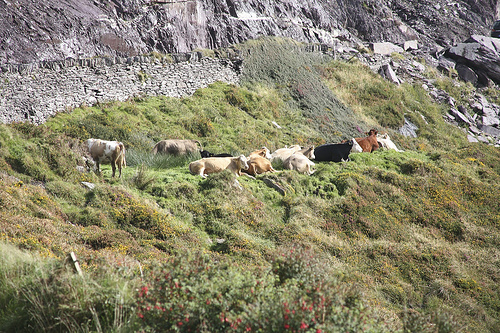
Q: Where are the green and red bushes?
A: Front of grass.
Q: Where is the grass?
A: Behind the bushes.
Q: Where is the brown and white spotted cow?
A: Left of the other animals.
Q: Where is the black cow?
A: Next to the deep brown animal.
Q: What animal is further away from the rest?
A: Left spotted cow.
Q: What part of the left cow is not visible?
A: Head.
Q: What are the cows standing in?
A: Grass.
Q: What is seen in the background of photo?
A: Rock.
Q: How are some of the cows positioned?
A: Laying down.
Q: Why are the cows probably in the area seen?
A: It's sunny.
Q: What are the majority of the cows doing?
A: Laying down.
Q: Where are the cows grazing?
A: Mountain side.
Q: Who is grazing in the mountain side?
A: Cows.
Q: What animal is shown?
A: Cows.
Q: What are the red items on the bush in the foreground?
A: Little flowers.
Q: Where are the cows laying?
A: In a patch of grass.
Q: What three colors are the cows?
A: White, brown and black.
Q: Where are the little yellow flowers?
A: Scattered throughout grass.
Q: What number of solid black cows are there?
A: 2.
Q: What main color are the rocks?
A: Grey.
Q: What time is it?
A: Afternoon.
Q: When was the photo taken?
A: During the daytime.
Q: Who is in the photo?
A: Animals.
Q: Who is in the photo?
A: No people.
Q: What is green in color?
A: Grass.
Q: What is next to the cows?
A: Rocks.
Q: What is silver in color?
A: Rocks.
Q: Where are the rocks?
A: On the mountain.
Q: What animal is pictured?
A: Cows.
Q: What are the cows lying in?
A: Grass.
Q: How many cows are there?
A: Nine.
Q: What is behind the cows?
A: Rock.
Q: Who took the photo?
A: Farmer.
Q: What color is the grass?
A: Green.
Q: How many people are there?
A: Zero.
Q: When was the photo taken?
A: Morning.